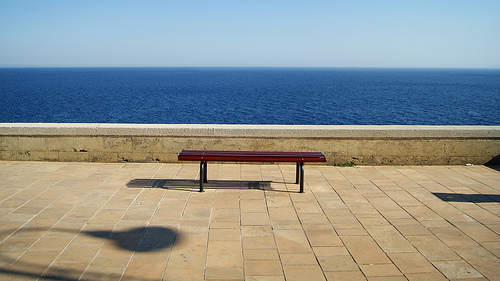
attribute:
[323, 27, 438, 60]
clouds — white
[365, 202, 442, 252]
tiels — cream color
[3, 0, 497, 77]
sky — light blue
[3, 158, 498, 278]
ground — brick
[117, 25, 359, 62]
clouds — white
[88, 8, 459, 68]
sky — blue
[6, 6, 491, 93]
sky — blue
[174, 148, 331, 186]
bench — wooden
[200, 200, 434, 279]
floor — stone, tiled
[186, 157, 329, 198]
steel — black, coated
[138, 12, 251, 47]
sky — blue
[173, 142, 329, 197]
bench — wooden, red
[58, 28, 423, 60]
clouds — white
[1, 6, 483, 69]
sky — blue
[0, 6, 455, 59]
clouds — white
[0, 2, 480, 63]
sky — blue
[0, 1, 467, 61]
clouds — white